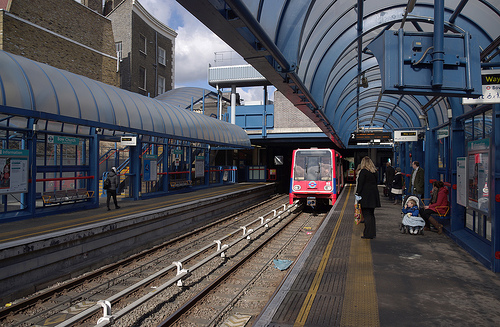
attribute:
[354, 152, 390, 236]
woman — standing, white, tall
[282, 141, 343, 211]
train — red, small, moving, tiny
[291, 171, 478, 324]
ground — black, grey, short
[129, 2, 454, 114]
sky — white, cloudy, blue